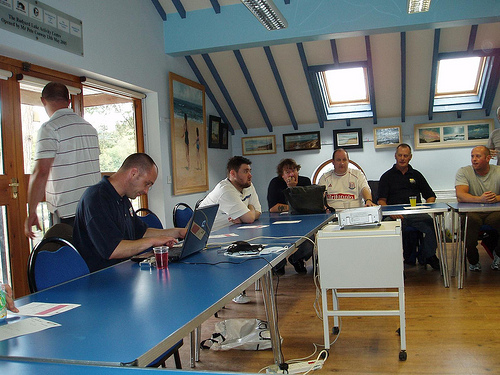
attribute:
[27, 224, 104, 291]
chair — blue, desk chair 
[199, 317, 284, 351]
bag — plastic bag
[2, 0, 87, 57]
banner — gray, white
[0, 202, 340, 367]
table — long, blue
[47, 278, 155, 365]
table — blue , shiny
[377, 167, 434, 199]
shirt — black 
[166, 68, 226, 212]
artwork — wood framed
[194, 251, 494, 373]
floor — light colored, hard wood 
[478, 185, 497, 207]
hands — clasped together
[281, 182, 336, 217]
bag — black 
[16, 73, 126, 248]
men — six, sitting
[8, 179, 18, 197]
doorknob — golden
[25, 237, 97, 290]
chair — empty, blue , black 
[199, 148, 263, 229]
hair — dark 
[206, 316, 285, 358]
bag — shopping bag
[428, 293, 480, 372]
floor — light brown wood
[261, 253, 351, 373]
strip — power 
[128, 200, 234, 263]
laptop — computer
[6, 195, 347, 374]
table — blue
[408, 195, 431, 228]
juice — orange